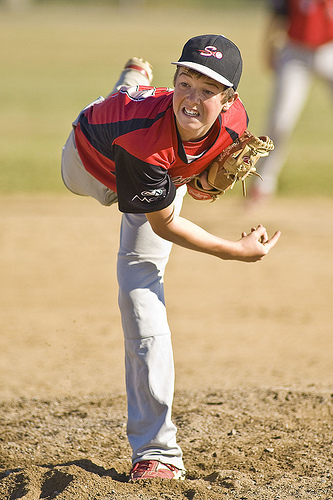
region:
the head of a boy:
[165, 30, 245, 135]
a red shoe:
[125, 446, 194, 488]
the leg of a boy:
[111, 202, 186, 459]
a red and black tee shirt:
[68, 82, 255, 220]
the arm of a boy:
[112, 146, 239, 267]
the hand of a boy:
[235, 222, 282, 267]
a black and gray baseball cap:
[169, 30, 245, 94]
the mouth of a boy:
[179, 106, 202, 121]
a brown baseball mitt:
[184, 127, 277, 204]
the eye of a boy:
[197, 84, 218, 99]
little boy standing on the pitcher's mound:
[48, 28, 266, 495]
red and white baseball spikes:
[122, 458, 190, 491]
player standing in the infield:
[245, 1, 332, 199]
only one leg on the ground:
[93, 223, 225, 492]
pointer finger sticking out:
[237, 221, 284, 268]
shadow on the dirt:
[37, 445, 120, 484]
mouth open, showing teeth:
[179, 103, 202, 122]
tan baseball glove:
[196, 127, 271, 196]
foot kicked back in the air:
[112, 56, 158, 86]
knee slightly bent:
[105, 251, 180, 338]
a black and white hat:
[165, 30, 253, 97]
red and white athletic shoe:
[120, 446, 200, 490]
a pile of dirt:
[6, 446, 103, 495]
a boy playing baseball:
[60, 21, 283, 447]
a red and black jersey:
[52, 69, 269, 224]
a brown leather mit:
[181, 129, 280, 204]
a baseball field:
[0, 88, 328, 471]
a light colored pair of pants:
[251, 39, 331, 187]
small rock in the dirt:
[228, 427, 242, 438]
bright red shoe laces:
[128, 448, 168, 476]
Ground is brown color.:
[203, 399, 326, 485]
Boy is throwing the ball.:
[50, 32, 283, 487]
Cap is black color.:
[176, 31, 254, 84]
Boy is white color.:
[112, 235, 193, 444]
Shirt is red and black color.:
[86, 115, 158, 183]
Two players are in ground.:
[82, 14, 316, 219]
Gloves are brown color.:
[205, 133, 275, 212]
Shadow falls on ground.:
[9, 437, 131, 499]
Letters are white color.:
[131, 184, 170, 209]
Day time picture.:
[13, 15, 314, 467]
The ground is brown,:
[216, 379, 255, 469]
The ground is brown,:
[220, 365, 278, 467]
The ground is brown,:
[250, 327, 325, 482]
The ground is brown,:
[233, 427, 244, 446]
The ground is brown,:
[172, 341, 245, 496]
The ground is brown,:
[218, 381, 296, 498]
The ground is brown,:
[248, 388, 281, 497]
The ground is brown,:
[238, 391, 260, 430]